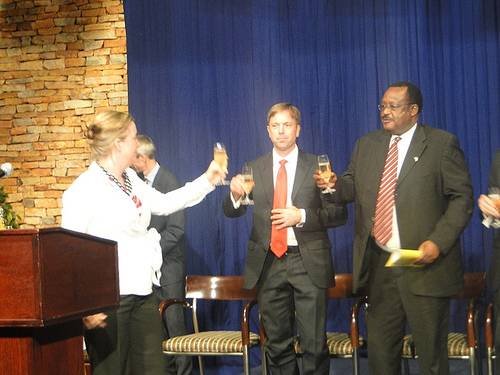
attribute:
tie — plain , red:
[262, 138, 302, 245]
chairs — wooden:
[146, 267, 481, 349]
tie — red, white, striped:
[372, 134, 402, 246]